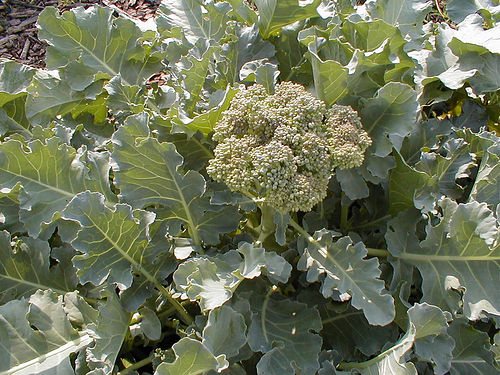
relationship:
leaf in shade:
[243, 285, 323, 372] [286, 281, 324, 314]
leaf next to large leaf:
[85, 130, 212, 265] [0, 132, 132, 248]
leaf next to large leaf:
[108, 107, 237, 247] [330, 81, 421, 201]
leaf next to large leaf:
[236, 283, 333, 373] [301, 284, 413, 367]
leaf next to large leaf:
[31, 2, 169, 111] [0, 132, 132, 248]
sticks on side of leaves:
[130, 4, 147, 14] [237, 239, 386, 333]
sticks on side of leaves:
[7, 6, 36, 20] [237, 239, 386, 333]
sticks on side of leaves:
[32, 44, 44, 58] [237, 239, 386, 333]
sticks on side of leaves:
[16, 36, 32, 58] [237, 239, 386, 333]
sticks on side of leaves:
[17, 17, 37, 29] [237, 239, 386, 333]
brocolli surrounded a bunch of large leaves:
[205, 81, 373, 213] [2, 3, 484, 373]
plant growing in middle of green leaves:
[205, 78, 372, 215] [456, 116, 496, 235]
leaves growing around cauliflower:
[2, 3, 484, 373] [202, 69, 373, 217]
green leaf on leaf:
[382, 203, 498, 316] [388, 199, 477, 315]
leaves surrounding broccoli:
[405, 3, 499, 90] [154, 62, 386, 248]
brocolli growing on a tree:
[205, 81, 373, 213] [75, 42, 216, 293]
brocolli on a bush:
[225, 105, 324, 202] [0, 1, 496, 370]